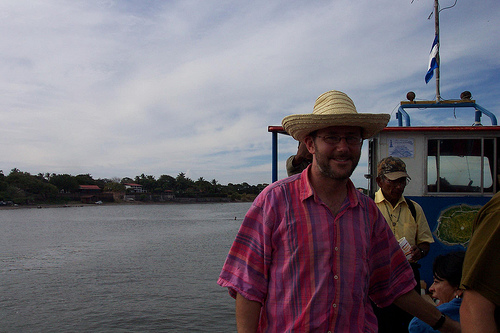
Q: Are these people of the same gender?
A: No, they are both male and female.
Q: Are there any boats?
A: Yes, there is a boat.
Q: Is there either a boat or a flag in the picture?
A: Yes, there is a boat.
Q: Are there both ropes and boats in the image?
A: No, there is a boat but no ropes.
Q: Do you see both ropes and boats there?
A: No, there is a boat but no ropes.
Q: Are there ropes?
A: No, there are no ropes.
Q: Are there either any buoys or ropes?
A: No, there are no ropes or buoys.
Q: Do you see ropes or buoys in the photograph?
A: No, there are no ropes or buoys.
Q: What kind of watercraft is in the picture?
A: The watercraft is a boat.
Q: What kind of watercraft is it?
A: The watercraft is a boat.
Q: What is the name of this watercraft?
A: This is a boat.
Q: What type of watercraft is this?
A: This is a boat.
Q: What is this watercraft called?
A: This is a boat.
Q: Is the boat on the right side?
A: Yes, the boat is on the right of the image.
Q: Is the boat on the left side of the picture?
A: No, the boat is on the right of the image.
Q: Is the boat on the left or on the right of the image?
A: The boat is on the right of the image.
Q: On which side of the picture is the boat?
A: The boat is on the right of the image.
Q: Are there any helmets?
A: No, there are no helmets.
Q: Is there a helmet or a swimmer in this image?
A: No, there are no helmets or swimmers.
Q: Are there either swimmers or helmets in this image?
A: No, there are no helmets or swimmers.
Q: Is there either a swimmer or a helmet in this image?
A: No, there are no helmets or swimmers.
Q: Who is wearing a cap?
A: The man is wearing a cap.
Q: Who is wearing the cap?
A: The man is wearing a cap.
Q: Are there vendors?
A: No, there are no vendors.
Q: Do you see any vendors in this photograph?
A: No, there are no vendors.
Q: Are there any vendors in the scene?
A: No, there are no vendors.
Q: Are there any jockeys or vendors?
A: No, there are no vendors or jockeys.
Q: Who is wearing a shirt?
A: The man is wearing a shirt.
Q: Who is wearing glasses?
A: The man is wearing glasses.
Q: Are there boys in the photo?
A: No, there are no boys.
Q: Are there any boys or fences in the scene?
A: No, there are no boys or fences.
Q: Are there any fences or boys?
A: No, there are no boys or fences.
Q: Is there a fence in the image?
A: No, there are no fences.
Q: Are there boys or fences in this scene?
A: No, there are no fences or boys.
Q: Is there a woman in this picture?
A: Yes, there is a woman.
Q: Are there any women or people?
A: Yes, there is a woman.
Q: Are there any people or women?
A: Yes, there is a woman.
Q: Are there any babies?
A: No, there are no babies.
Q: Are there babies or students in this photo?
A: No, there are no babies or students.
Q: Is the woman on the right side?
A: Yes, the woman is on the right of the image.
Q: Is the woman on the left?
A: No, the woman is on the right of the image.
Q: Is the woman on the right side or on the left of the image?
A: The woman is on the right of the image.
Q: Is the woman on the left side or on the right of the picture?
A: The woman is on the right of the image.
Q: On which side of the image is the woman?
A: The woman is on the right of the image.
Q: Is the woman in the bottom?
A: Yes, the woman is in the bottom of the image.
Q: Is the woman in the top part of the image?
A: No, the woman is in the bottom of the image.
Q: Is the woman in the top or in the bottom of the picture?
A: The woman is in the bottom of the image.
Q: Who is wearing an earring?
A: The woman is wearing an earring.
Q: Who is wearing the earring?
A: The woman is wearing an earring.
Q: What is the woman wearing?
A: The woman is wearing an earring.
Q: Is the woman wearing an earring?
A: Yes, the woman is wearing an earring.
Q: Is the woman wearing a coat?
A: No, the woman is wearing an earring.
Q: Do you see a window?
A: Yes, there is a window.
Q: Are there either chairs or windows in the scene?
A: Yes, there is a window.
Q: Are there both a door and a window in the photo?
A: No, there is a window but no doors.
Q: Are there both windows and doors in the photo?
A: No, there is a window but no doors.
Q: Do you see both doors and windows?
A: No, there is a window but no doors.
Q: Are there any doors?
A: No, there are no doors.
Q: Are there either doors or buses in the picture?
A: No, there are no doors or buses.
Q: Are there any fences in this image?
A: No, there are no fences.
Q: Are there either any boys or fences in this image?
A: No, there are no fences or boys.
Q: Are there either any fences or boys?
A: No, there are no fences or boys.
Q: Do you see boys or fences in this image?
A: No, there are no fences or boys.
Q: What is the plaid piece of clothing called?
A: The clothing item is a shirt.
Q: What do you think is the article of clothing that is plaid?
A: The clothing item is a shirt.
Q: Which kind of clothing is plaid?
A: The clothing is a shirt.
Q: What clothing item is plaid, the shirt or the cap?
A: The shirt is plaid.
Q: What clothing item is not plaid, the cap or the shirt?
A: The cap is not plaid.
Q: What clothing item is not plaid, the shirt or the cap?
A: The cap is not plaid.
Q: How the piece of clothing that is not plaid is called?
A: The clothing item is a cap.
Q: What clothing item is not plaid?
A: The clothing item is a cap.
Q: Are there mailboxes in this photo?
A: No, there are no mailboxes.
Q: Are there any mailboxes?
A: No, there are no mailboxes.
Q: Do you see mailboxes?
A: No, there are no mailboxes.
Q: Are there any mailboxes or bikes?
A: No, there are no mailboxes or bikes.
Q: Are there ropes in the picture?
A: No, there are no ropes.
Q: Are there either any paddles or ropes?
A: No, there are no ropes or paddles.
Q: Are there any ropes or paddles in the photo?
A: No, there are no ropes or paddles.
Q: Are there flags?
A: Yes, there is a flag.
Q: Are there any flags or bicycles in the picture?
A: Yes, there is a flag.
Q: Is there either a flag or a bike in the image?
A: Yes, there is a flag.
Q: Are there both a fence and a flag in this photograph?
A: No, there is a flag but no fences.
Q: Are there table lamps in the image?
A: No, there are no table lamps.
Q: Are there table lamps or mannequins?
A: No, there are no table lamps or mannequins.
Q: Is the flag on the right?
A: Yes, the flag is on the right of the image.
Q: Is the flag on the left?
A: No, the flag is on the right of the image.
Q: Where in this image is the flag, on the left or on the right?
A: The flag is on the right of the image.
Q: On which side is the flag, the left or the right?
A: The flag is on the right of the image.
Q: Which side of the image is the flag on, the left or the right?
A: The flag is on the right of the image.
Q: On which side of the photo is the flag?
A: The flag is on the right of the image.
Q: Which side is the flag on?
A: The flag is on the right of the image.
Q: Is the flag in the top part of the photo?
A: Yes, the flag is in the top of the image.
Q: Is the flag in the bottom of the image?
A: No, the flag is in the top of the image.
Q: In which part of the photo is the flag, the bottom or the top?
A: The flag is in the top of the image.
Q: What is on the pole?
A: The flag is on the pole.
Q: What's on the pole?
A: The flag is on the pole.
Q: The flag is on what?
A: The flag is on the pole.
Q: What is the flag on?
A: The flag is on the pole.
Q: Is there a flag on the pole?
A: Yes, there is a flag on the pole.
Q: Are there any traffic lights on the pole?
A: No, there is a flag on the pole.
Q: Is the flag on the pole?
A: Yes, the flag is on the pole.